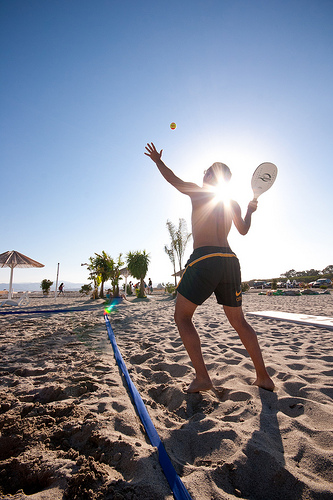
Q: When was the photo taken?
A: Daytime.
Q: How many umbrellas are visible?
A: One.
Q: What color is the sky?
A: Blue.